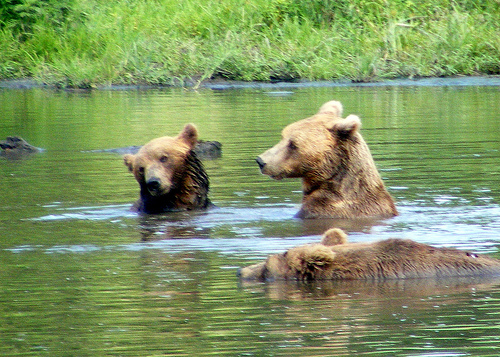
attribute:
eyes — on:
[133, 149, 173, 178]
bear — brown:
[112, 117, 219, 222]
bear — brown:
[230, 227, 494, 296]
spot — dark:
[176, 148, 209, 210]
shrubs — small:
[6, 0, 496, 82]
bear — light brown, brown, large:
[253, 97, 400, 223]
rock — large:
[182, 129, 230, 171]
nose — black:
[146, 175, 161, 192]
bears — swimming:
[123, 97, 488, 296]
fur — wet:
[133, 153, 210, 211]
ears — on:
[318, 96, 345, 116]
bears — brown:
[121, 122, 498, 313]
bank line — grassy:
[1, 0, 499, 88]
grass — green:
[12, 4, 494, 68]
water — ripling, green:
[6, 83, 498, 350]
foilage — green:
[12, 4, 488, 74]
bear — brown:
[209, 104, 410, 288]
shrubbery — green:
[10, 4, 470, 63]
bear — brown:
[236, 226, 497, 284]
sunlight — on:
[224, 201, 271, 231]